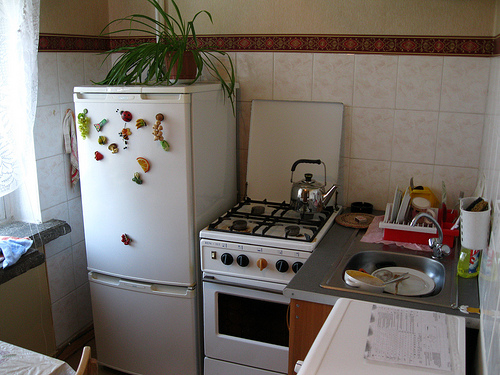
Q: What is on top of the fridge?
A: Plant.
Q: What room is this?
A: Kitchen.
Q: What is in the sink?
A: Dishes.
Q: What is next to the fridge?
A: Stove.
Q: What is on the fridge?
A: Magnets.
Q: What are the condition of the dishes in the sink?
A: Dirty.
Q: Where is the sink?
A: Right side.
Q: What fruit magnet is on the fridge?
A: Orange.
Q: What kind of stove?
A: Gas.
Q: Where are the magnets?
A: On fridge.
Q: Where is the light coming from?
A: Window.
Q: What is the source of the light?
A: Sun.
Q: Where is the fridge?
A: Corner.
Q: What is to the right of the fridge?
A: Stove.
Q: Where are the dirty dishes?
A: Sink.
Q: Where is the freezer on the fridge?
A: Bottom.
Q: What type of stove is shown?
A: Gas.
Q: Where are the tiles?
A: On wall.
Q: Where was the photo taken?
A: Kitchen.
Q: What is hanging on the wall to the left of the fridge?
A: A rag.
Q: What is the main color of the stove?
A: White.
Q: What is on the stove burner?
A: Kettle.